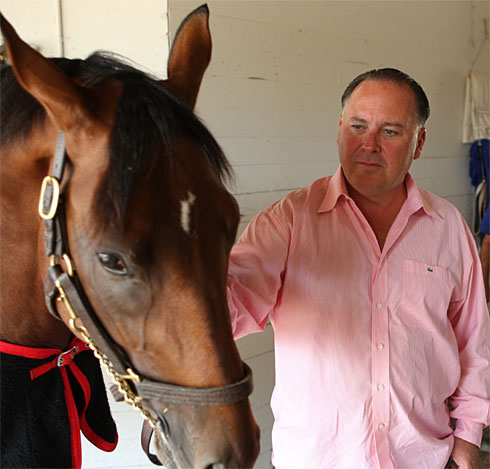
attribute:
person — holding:
[226, 68, 489, 469]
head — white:
[337, 65, 428, 188]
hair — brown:
[341, 68, 430, 123]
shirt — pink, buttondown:
[228, 163, 489, 467]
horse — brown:
[3, 2, 259, 468]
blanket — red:
[2, 335, 118, 469]